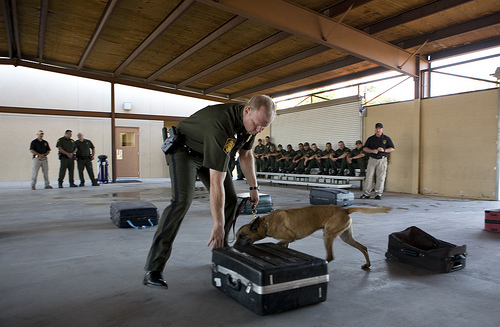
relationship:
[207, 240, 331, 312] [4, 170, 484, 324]
case on floor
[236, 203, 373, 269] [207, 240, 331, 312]
brown dog sniffing case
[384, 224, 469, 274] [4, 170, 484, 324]
suitcase on floor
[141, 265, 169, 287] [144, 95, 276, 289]
shoe on officer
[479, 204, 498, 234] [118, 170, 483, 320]
suitcase on floor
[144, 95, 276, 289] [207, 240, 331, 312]
officer bending down in front of case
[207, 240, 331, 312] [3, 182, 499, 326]
case on floor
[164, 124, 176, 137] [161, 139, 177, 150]
gun in holster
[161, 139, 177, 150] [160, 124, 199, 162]
holster on hip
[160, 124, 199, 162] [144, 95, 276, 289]
hip of officer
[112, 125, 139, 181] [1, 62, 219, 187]
door on wall